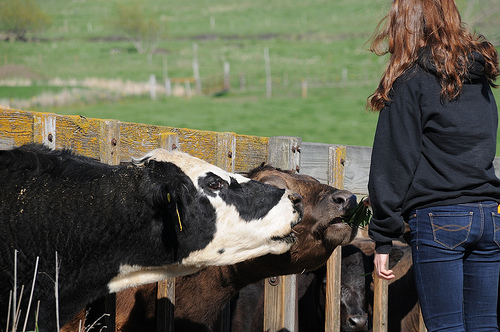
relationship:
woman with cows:
[364, 2, 495, 330] [1, 144, 404, 331]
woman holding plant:
[364, 2, 495, 330] [345, 194, 374, 243]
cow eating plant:
[69, 167, 365, 327] [345, 194, 374, 243]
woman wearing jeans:
[364, 2, 495, 330] [406, 197, 497, 331]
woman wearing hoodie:
[364, 2, 495, 330] [367, 47, 499, 259]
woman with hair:
[364, 2, 495, 330] [367, 0, 496, 111]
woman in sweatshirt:
[364, 2, 495, 330] [367, 47, 499, 259]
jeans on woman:
[406, 197, 497, 331] [364, 2, 495, 330]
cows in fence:
[1, 144, 404, 331] [1, 106, 376, 198]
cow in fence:
[234, 245, 404, 330] [1, 106, 376, 198]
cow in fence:
[69, 167, 365, 327] [1, 106, 376, 198]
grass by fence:
[2, 3, 499, 152] [1, 106, 376, 198]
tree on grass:
[110, 3, 161, 61] [2, 3, 499, 152]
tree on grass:
[0, 2, 53, 42] [2, 3, 499, 152]